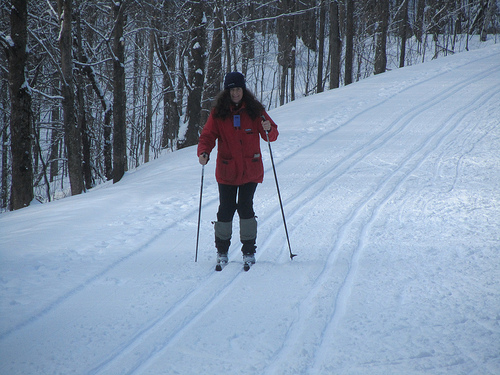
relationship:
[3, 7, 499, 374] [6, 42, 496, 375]
tracks in snow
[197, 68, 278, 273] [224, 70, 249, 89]
woman wearing a hat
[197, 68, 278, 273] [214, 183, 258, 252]
woman wearing leg warmers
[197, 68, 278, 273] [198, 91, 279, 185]
woman wearing a red coat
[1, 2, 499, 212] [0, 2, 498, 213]
trees have snow on them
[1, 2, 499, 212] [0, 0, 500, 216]
trees have no leaves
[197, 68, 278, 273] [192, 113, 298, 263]
woman holding ski poles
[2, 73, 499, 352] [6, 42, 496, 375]
sun on snow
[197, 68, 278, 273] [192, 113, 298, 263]
woman standing on skis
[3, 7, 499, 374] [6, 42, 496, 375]
ski tracks on snow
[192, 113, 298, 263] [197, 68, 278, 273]
ski poles of woman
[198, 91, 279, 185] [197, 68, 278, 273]
red jacket of woman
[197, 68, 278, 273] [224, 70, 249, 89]
woman has a beanie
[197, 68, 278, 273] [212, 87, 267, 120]
woman has long hair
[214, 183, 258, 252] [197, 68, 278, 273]
dark pants of woman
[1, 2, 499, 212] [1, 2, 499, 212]
trees in a trees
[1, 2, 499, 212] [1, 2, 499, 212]
trees covered tree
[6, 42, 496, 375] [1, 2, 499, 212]
snow in a trees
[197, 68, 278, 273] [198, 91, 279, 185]
woman wearing a red jacket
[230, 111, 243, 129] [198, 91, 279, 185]
blue tag on jacket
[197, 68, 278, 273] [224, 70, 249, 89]
woman wearing a beanie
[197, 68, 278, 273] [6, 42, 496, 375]
skier in snow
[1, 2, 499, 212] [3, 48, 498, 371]
trees lining trail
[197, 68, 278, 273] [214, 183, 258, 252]
woman wearing pants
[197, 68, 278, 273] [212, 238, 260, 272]
woman wearing boots